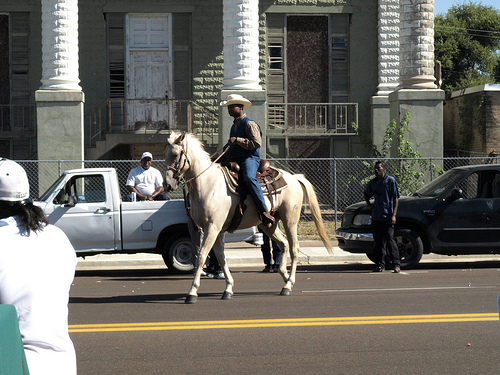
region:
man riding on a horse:
[151, 54, 281, 239]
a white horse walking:
[150, 84, 336, 267]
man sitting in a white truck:
[35, 138, 182, 239]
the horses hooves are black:
[168, 282, 298, 306]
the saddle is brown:
[205, 137, 278, 222]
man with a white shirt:
[121, 130, 163, 191]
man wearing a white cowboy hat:
[204, 91, 257, 112]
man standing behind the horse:
[327, 133, 412, 282]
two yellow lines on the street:
[182, 296, 485, 340]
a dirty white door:
[109, 1, 177, 121]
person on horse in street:
[109, 77, 354, 322]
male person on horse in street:
[106, 73, 346, 335]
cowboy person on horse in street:
[121, 78, 356, 323]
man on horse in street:
[135, 78, 360, 323]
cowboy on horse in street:
[137, 77, 344, 332]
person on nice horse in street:
[113, 83, 348, 312]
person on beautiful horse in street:
[113, 78, 335, 317]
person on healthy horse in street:
[127, 78, 331, 312]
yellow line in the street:
[85, 311, 453, 341]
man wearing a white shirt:
[124, 149, 174, 202]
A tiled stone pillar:
[397, 0, 451, 108]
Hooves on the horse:
[175, 267, 332, 308]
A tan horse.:
[155, 131, 342, 313]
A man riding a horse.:
[140, 85, 388, 332]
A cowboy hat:
[212, 89, 257, 114]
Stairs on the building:
[80, 112, 138, 159]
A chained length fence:
[20, 158, 497, 283]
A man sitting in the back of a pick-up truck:
[124, 146, 176, 218]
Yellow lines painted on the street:
[66, 310, 498, 334]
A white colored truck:
[0, 152, 294, 279]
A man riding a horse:
[163, 90, 344, 309]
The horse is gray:
[159, 131, 338, 285]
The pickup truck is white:
[26, 166, 211, 261]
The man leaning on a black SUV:
[366, 160, 410, 277]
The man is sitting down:
[111, 144, 176, 199]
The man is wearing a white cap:
[123, 149, 170, 200]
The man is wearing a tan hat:
[221, 93, 256, 111]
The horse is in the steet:
[154, 127, 330, 313]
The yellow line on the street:
[73, 302, 499, 332]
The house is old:
[7, 2, 455, 193]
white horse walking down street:
[157, 127, 337, 306]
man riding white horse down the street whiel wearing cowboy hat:
[150, 78, 342, 310]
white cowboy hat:
[215, 92, 254, 111]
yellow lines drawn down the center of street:
[101, 308, 499, 336]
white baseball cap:
[2, 156, 30, 203]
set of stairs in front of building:
[82, 98, 227, 160]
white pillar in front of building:
[218, 0, 266, 108]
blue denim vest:
[225, 115, 265, 154]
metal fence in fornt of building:
[275, 155, 491, 256]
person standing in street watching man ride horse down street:
[360, 156, 406, 277]